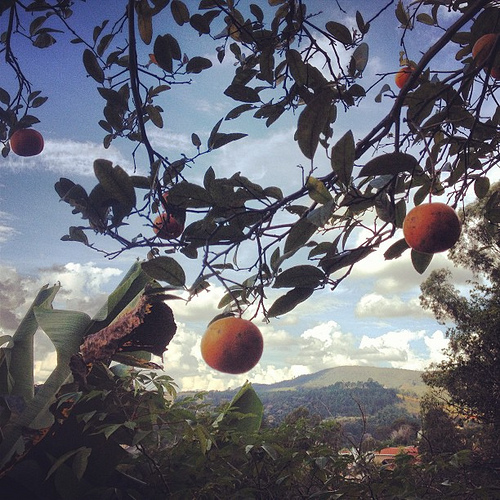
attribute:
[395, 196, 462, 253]
orange — hanging, growing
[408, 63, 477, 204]
branch — brown, small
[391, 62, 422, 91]
orange — hanging, small, growing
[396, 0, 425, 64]
branch — brown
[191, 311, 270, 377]
orange — hanging, growing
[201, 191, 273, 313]
branch — brown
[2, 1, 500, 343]
tree — orange, large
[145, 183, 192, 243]
oranges — together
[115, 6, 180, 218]
branch — brown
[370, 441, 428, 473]
house — in view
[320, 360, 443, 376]
top — green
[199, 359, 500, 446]
mountain — grassy, background, countryside, green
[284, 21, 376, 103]
clouds — white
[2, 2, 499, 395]
sky — cloudy, blue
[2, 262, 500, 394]
clouds — white, large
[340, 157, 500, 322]
clouds — white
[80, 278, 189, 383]
leaf — banana, drying, dead, brown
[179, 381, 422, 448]
area — wooded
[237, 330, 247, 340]
spots — dark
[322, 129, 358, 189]
leaves — green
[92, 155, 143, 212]
leaves — green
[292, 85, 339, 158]
leaves — green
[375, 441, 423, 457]
roof — red